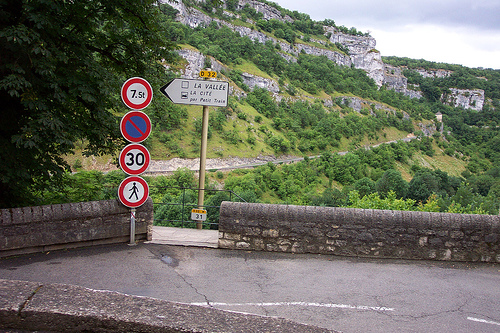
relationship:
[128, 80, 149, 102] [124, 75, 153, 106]
7.5t on sign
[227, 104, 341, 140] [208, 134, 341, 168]
bushes by road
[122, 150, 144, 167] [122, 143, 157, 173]
30 on sign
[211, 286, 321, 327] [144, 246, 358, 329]
stripes on road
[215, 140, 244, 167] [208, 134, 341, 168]
rocks on road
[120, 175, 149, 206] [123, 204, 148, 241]
signs on pole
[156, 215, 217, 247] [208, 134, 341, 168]
walkway by road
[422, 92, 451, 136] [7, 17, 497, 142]
buidling in distance